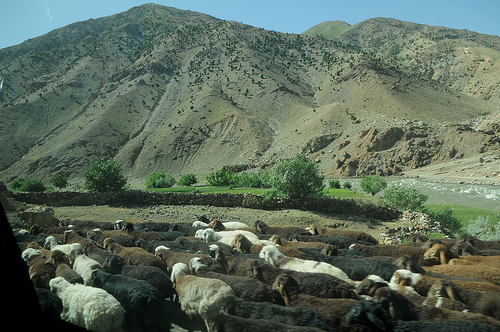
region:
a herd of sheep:
[11, 214, 499, 330]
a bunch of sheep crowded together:
[17, 211, 499, 329]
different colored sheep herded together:
[11, 212, 498, 330]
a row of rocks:
[9, 185, 454, 245]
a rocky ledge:
[6, 183, 456, 241]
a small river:
[285, 171, 497, 220]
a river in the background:
[316, 173, 498, 215]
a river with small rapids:
[308, 173, 498, 214]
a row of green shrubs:
[3, 155, 465, 234]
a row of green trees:
[6, 151, 466, 235]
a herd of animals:
[9, 192, 499, 330]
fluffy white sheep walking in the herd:
[50, 278, 130, 328]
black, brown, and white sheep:
[8, 196, 497, 331]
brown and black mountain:
[2, 0, 497, 175]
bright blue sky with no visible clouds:
[2, 2, 499, 44]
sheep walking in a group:
[7, 202, 499, 327]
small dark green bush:
[272, 151, 321, 203]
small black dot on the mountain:
[187, 103, 198, 114]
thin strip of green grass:
[137, 177, 487, 225]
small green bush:
[173, 168, 201, 188]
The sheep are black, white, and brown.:
[18, 220, 498, 330]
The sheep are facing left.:
[0, 204, 497, 329]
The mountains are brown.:
[1, 1, 498, 181]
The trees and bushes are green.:
[10, 155, 499, 237]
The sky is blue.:
[1, 0, 498, 47]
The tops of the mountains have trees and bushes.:
[1, 3, 497, 82]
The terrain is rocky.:
[324, 110, 499, 178]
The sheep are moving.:
[3, 216, 497, 330]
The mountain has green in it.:
[301, 19, 355, 40]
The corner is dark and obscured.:
[0, 197, 49, 329]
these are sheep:
[7, 198, 499, 330]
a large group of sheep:
[4, 205, 498, 330]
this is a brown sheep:
[415, 255, 495, 285]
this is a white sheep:
[247, 242, 352, 288]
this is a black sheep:
[80, 265, 165, 330]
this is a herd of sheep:
[6, 200, 496, 325]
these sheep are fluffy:
[6, 196, 496, 326]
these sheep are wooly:
[11, 210, 496, 325]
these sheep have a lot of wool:
[6, 205, 496, 326]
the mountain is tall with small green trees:
[0, 2, 496, 203]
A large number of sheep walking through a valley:
[16, 203, 492, 326]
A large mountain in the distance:
[14, 12, 492, 187]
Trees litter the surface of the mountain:
[196, 28, 307, 88]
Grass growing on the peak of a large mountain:
[298, 13, 358, 46]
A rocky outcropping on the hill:
[396, 146, 431, 170]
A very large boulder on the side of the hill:
[362, 122, 412, 157]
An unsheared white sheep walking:
[48, 274, 116, 326]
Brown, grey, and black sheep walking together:
[5, 214, 492, 326]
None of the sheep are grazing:
[37, 215, 484, 320]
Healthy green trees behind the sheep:
[266, 155, 330, 207]